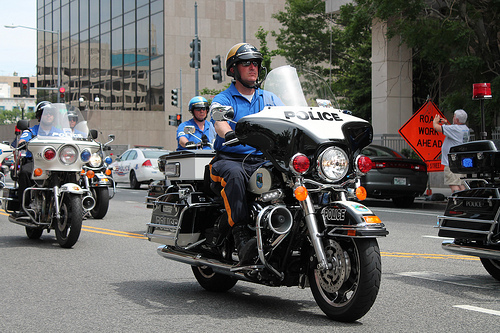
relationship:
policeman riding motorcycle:
[175, 95, 215, 150] [146, 147, 216, 208]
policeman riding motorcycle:
[15, 98, 64, 209] [1, 103, 100, 242]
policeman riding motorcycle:
[207, 40, 290, 255] [147, 64, 389, 320]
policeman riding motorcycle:
[67, 109, 77, 130] [70, 106, 119, 219]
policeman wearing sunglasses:
[207, 40, 290, 255] [238, 60, 261, 68]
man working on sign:
[431, 106, 472, 193] [397, 95, 449, 169]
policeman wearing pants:
[207, 40, 290, 255] [209, 155, 262, 232]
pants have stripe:
[209, 155, 262, 232] [208, 161, 233, 226]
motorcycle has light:
[1, 103, 100, 242] [44, 148, 58, 159]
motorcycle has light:
[1, 103, 100, 242] [79, 149, 93, 163]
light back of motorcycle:
[469, 80, 493, 99] [434, 80, 500, 279]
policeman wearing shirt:
[207, 40, 290, 255] [210, 84, 284, 154]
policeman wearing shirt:
[15, 98, 64, 209] [20, 124, 66, 157]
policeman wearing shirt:
[175, 95, 215, 150] [177, 119, 216, 143]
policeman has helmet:
[175, 95, 215, 150] [187, 94, 210, 110]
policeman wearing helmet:
[207, 40, 290, 255] [224, 43, 263, 76]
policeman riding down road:
[207, 40, 290, 255] [2, 183, 499, 328]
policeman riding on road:
[15, 98, 64, 209] [2, 183, 499, 328]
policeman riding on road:
[67, 109, 77, 130] [2, 183, 499, 328]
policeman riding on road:
[175, 95, 215, 150] [2, 183, 499, 328]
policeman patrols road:
[207, 40, 290, 255] [2, 183, 499, 328]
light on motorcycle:
[293, 153, 311, 172] [147, 64, 389, 320]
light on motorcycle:
[357, 153, 371, 174] [147, 64, 389, 320]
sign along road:
[397, 95, 449, 169] [2, 183, 499, 328]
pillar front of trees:
[369, 17, 414, 154] [273, 1, 496, 128]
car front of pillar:
[353, 144, 428, 207] [369, 17, 414, 154]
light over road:
[4, 21, 18, 31] [2, 183, 499, 328]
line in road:
[1, 207, 481, 265] [2, 183, 499, 328]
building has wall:
[34, 1, 319, 149] [33, 2, 167, 146]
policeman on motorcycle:
[207, 40, 290, 255] [147, 64, 389, 320]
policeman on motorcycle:
[15, 98, 64, 209] [1, 103, 100, 242]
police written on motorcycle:
[283, 108, 343, 123] [147, 64, 389, 320]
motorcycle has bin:
[147, 64, 389, 320] [160, 148, 218, 180]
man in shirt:
[431, 106, 472, 193] [440, 121, 470, 165]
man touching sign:
[431, 106, 472, 193] [397, 95, 449, 169]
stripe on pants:
[208, 161, 233, 226] [209, 155, 262, 232]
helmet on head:
[224, 43, 263, 76] [226, 42, 264, 90]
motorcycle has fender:
[147, 64, 389, 320] [320, 199, 390, 236]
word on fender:
[321, 207, 347, 222] [320, 199, 390, 236]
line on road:
[1, 207, 481, 265] [2, 183, 499, 328]